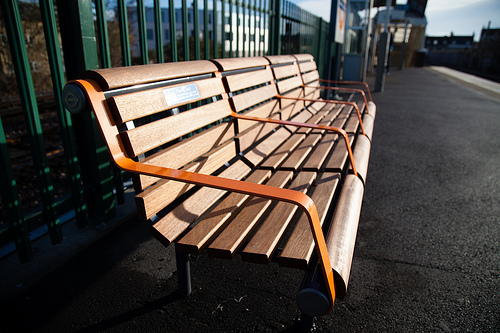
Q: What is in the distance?
A: Buildings.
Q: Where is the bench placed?
A: On the sidewalk.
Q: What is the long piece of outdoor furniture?
A: Bench.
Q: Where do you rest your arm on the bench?
A: Arm rest.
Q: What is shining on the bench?
A: Sun.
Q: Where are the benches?
A: Along a fence.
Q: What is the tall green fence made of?
A: Iron.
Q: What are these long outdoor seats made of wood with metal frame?
A: Benches.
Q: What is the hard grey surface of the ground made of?
A: Concrete.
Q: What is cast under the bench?
A: Shadow.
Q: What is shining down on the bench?
A: Sunshine.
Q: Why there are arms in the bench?
A: For the arms to rest.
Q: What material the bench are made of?
A: Wood.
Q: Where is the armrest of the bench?
A: On the side.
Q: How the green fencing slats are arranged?
A: Vertically.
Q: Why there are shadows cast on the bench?
A: Sun.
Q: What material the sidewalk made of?
A: Asphalt.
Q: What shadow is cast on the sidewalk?
A: Pole.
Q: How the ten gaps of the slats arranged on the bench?
A: Equally.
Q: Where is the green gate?
A: Behind the benches.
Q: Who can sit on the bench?
A: Any body.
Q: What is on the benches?
A: Armrests.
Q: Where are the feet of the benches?
A: On the ground.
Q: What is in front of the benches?
A: Sidewalk.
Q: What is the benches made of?
A: Wood.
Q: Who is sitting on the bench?
A: No person.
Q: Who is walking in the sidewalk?
A: No person.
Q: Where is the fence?
A: Behind the bench.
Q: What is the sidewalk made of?
A: Concrete.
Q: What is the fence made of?
A: Metal.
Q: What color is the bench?
A: Brown.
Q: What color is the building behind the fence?
A: White.